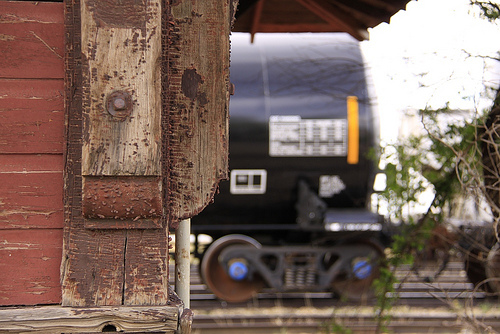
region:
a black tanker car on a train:
[199, 31, 387, 301]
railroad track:
[187, 275, 496, 305]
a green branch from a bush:
[350, 103, 499, 328]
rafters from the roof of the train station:
[245, 3, 400, 40]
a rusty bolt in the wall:
[107, 90, 129, 112]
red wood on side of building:
[0, 10, 60, 301]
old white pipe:
[172, 221, 187, 311]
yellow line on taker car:
[345, 95, 357, 165]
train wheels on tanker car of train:
[202, 240, 387, 301]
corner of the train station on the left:
[2, 5, 226, 330]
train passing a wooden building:
[15, 10, 486, 310]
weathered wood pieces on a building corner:
[0, 6, 225, 326]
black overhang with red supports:
[230, 0, 405, 41]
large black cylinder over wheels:
[195, 30, 380, 235]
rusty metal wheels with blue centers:
[200, 235, 382, 300]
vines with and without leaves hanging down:
[370, 86, 490, 326]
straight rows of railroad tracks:
[172, 255, 492, 325]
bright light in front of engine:
[362, 0, 492, 167]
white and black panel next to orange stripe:
[266, 91, 356, 161]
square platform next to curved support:
[292, 185, 380, 235]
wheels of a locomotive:
[195, 230, 395, 320]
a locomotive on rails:
[210, 28, 450, 309]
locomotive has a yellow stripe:
[195, 25, 395, 310]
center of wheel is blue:
[315, 235, 395, 301]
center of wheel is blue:
[190, 226, 270, 306]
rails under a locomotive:
[195, 230, 475, 310]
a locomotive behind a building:
[2, 2, 413, 332]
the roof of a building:
[217, 0, 419, 50]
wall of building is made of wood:
[4, 5, 236, 332]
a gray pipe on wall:
[172, 203, 202, 318]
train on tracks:
[183, 8, 478, 305]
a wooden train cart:
[11, 3, 391, 320]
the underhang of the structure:
[223, 2, 405, 47]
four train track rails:
[182, 245, 477, 298]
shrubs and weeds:
[390, 77, 496, 312]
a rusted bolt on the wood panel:
[101, 72, 144, 127]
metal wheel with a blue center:
[190, 232, 266, 300]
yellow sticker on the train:
[343, 91, 368, 166]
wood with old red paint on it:
[0, 0, 70, 305]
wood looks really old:
[59, 1, 218, 323]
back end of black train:
[226, 22, 383, 304]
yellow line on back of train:
[334, 85, 371, 174]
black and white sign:
[266, 117, 351, 162]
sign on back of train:
[260, 103, 355, 165]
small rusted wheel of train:
[202, 236, 273, 306]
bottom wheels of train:
[198, 231, 383, 301]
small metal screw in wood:
[111, 90, 126, 108]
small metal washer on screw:
[109, 88, 123, 113]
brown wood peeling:
[108, 48, 214, 174]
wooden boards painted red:
[0, 75, 61, 137]